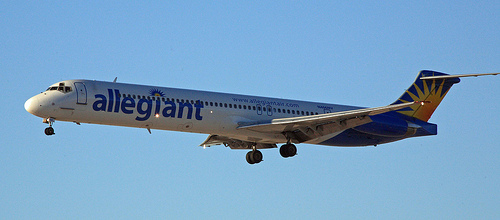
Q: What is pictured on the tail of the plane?
A: Sun.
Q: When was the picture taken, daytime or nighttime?
A: Daytime.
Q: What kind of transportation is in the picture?
A: Airplane.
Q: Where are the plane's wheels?
A: Down.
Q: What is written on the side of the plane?
A: Allegiant.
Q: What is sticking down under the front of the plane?
A: Front wheel.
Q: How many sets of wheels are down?
A: Three.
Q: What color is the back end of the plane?
A: Blue.